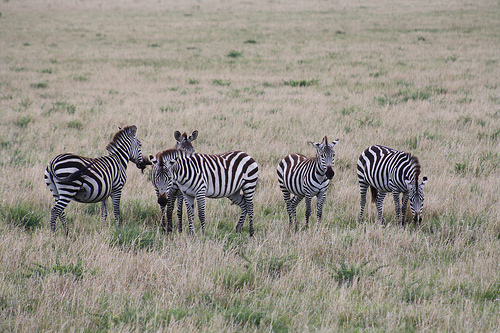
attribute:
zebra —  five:
[356, 138, 432, 235]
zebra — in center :
[151, 147, 271, 234]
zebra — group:
[31, 118, 149, 239]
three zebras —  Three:
[44, 126, 261, 236]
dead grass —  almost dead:
[312, 242, 391, 288]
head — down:
[146, 150, 180, 208]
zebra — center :
[42, 125, 430, 242]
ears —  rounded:
[171, 132, 215, 143]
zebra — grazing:
[400, 173, 435, 229]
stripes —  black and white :
[166, 154, 178, 167]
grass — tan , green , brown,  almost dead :
[0, 1, 499, 331]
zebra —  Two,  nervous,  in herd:
[37, 120, 450, 238]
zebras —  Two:
[348, 135, 432, 231]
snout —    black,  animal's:
[323, 167, 338, 183]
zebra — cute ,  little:
[355, 142, 427, 225]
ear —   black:
[420, 176, 427, 190]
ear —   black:
[403, 174, 410, 189]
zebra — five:
[361, 142, 433, 227]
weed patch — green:
[324, 255, 394, 282]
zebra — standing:
[44, 121, 156, 235]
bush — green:
[327, 256, 367, 287]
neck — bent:
[407, 172, 430, 192]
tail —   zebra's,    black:
[46, 160, 96, 181]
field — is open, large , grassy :
[6, 14, 497, 325]